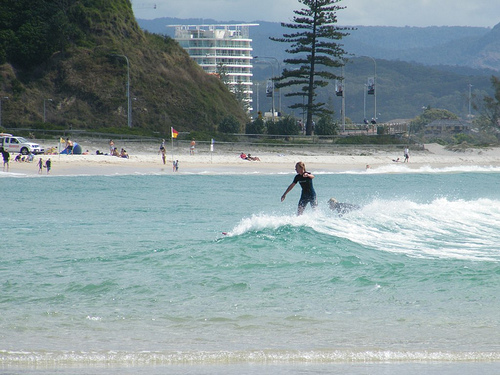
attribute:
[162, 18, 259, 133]
building — large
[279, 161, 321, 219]
person — white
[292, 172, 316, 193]
top — black 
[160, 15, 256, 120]
building — tall, white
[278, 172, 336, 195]
arm — out 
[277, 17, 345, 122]
evergreen tree — tall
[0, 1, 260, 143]
mountain — small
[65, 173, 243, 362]
wave — small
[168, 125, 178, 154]
flag — yellow, red 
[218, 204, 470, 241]
wave — small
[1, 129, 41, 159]
truck — white 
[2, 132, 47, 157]
vehicle — white , orange.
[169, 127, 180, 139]
flag — red, white, yellow., colors 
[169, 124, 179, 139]
flag — small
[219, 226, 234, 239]
surfboard tip — tip 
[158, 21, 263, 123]
building —  white 